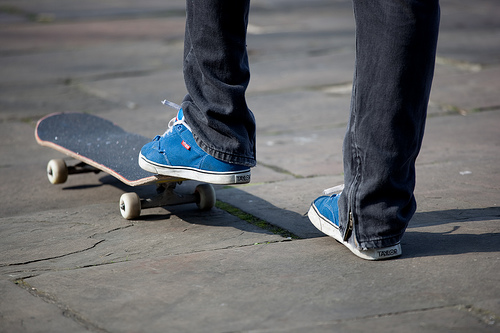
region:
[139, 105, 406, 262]
person is wearing blue kicks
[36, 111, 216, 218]
skateboard is under shoe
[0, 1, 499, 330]
ground is made od large stone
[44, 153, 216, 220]
skateboard has three white wheels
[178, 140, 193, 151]
red tag on blue shoe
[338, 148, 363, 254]
bottom of jean leg has zipper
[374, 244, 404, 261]
Back of right leg says TAYLOR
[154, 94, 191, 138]
white laces on blue shoe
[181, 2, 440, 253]
person is wearing black jeans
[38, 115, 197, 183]
black grip tape on skateboard top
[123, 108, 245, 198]
person wearing blue shoes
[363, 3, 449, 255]
person wearing black pants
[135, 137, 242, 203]
foot on a skate board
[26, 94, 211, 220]
skateboard on the sidewalk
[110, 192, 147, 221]
white wheels on a skateboard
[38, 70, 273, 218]
person on a skateboard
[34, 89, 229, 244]
person stake boarding on the street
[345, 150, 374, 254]
zipper on black pants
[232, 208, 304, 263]
cracks in the ground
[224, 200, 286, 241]
grass growing in the street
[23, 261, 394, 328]
tile laid in ground for walking on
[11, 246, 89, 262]
piece of tile flaked off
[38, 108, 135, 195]
skateboard used for boarding on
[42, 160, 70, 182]
wheels used for rolling skateboard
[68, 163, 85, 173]
axel used for holding skateboard wheels together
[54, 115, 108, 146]
rough surface for grip on soles of rubber shoes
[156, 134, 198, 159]
blue suede shoes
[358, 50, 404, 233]
blue jeans for leg protection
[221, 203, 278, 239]
space forming between two tiles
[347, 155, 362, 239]
zipper for jean cuffs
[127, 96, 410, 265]
person's shoes are blue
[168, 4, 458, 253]
person's jeans are black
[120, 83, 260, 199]
person's foot on skateboard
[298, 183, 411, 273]
person's foot on ground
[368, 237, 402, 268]
black letters on shoe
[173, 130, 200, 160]
red label on shoe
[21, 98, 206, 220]
the skateboard is black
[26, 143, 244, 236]
skateboard wheels are white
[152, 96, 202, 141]
shoe laces are white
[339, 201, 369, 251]
zipper pulled up on pants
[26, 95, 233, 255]
this is a skate board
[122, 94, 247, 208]
this is a rubber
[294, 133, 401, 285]
this is a rubber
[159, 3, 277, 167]
this is a leg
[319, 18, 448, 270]
this is a leg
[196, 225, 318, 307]
a stone in the ground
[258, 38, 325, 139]
a stone in the ground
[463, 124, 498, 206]
a stone in the ground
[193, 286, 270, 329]
a stone in the ground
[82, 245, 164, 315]
a stone in the ground